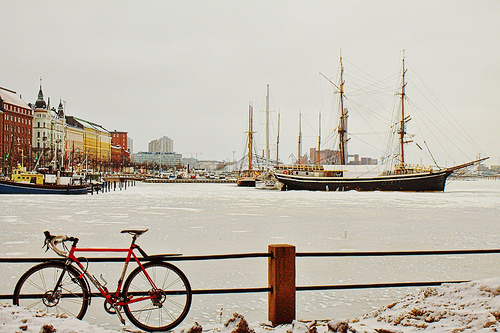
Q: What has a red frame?
A: The bike.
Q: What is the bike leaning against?
A: A rail.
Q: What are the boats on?
A: Water.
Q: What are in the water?
A: Boats.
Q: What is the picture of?
A: Waterfront.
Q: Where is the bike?
A: A bicycle is parked by a fence.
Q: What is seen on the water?
A: A ship and a few small boats.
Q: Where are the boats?
A: At a harbor on water.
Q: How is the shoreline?
A: Shoreline has many big buildings.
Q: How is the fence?
A: Red post and black metal beams.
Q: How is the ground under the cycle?
A: Rocky shore covered with snow.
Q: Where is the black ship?
A: Docked near the city.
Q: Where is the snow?
A: On the rocky shore where bike is parked.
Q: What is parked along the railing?
A: A red bicycle.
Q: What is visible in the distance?
A: A marina.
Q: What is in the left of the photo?
A: Rows of buildings and houses.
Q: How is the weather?
A: Grey and gloomy.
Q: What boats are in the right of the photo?
A: Large sailing vessels.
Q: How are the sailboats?
A: Docked with sails down.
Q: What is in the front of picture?
A: Bike.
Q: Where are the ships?
A: Water.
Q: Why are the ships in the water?
A: To sail.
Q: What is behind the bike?
A: Fence.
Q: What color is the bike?
A: Red.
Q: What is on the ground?
A: Snow.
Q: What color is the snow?
A: White.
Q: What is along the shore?
A: Buildings.